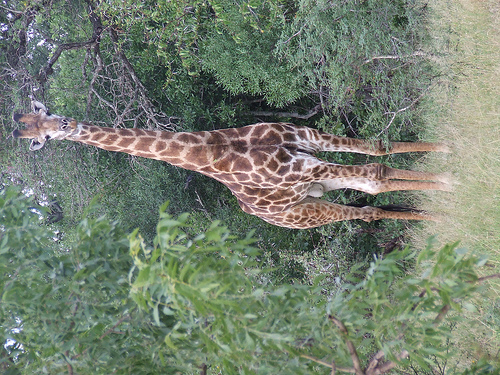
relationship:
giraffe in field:
[10, 99, 455, 232] [442, 3, 498, 370]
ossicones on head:
[7, 107, 33, 142] [12, 96, 471, 236]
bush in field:
[126, 199, 500, 374] [410, 0, 498, 373]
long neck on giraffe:
[78, 122, 209, 172] [10, 99, 455, 232]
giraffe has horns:
[10, 99, 455, 232] [10, 109, 32, 140]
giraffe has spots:
[10, 99, 455, 232] [225, 134, 290, 178]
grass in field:
[407, 8, 498, 273] [372, 0, 492, 364]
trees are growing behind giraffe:
[0, 183, 341, 367] [10, 99, 455, 232]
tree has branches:
[3, 1, 433, 204] [9, 37, 167, 139]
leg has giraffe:
[341, 137, 429, 157] [155, 129, 327, 253]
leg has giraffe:
[324, 161, 411, 181] [155, 129, 327, 253]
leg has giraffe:
[332, 202, 421, 228] [155, 129, 327, 253]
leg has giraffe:
[347, 180, 407, 194] [155, 129, 327, 253]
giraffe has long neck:
[0, 85, 449, 257] [78, 115, 209, 172]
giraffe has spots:
[10, 99, 455, 232] [221, 154, 261, 195]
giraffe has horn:
[10, 99, 455, 232] [10, 112, 33, 122]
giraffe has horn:
[10, 99, 455, 232] [12, 124, 31, 138]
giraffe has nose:
[10, 99, 455, 232] [55, 112, 80, 131]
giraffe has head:
[10, 99, 455, 232] [13, 100, 80, 154]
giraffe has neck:
[10, 99, 455, 232] [63, 118, 214, 175]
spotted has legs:
[257, 122, 378, 180] [263, 119, 458, 186]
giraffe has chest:
[10, 99, 455, 232] [230, 118, 295, 194]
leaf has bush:
[194, 258, 244, 297] [126, 197, 497, 372]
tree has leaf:
[3, 1, 433, 204] [173, 26, 220, 72]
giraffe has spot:
[10, 99, 455, 232] [132, 137, 156, 151]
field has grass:
[329, 0, 494, 374] [375, 0, 497, 369]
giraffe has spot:
[10, 99, 455, 232] [211, 151, 232, 174]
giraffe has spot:
[10, 99, 455, 232] [245, 146, 279, 169]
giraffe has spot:
[10, 99, 455, 232] [230, 136, 249, 157]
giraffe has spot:
[10, 99, 455, 232] [216, 126, 249, 141]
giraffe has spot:
[10, 99, 455, 232] [187, 146, 208, 167]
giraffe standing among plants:
[10, 99, 455, 232] [114, 0, 499, 370]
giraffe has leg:
[10, 99, 455, 232] [292, 120, 459, 153]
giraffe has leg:
[10, 99, 455, 232] [302, 157, 459, 184]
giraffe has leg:
[10, 99, 455, 232] [324, 182, 455, 195]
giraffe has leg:
[10, 99, 455, 232] [314, 200, 433, 223]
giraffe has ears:
[10, 99, 455, 232] [23, 96, 55, 159]